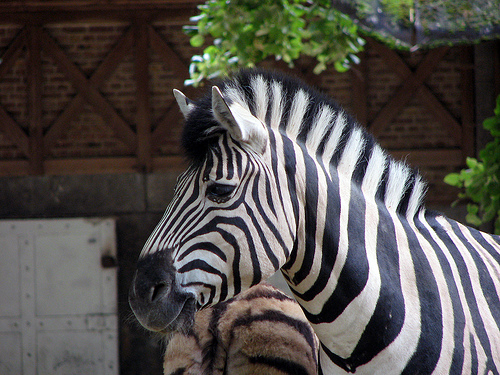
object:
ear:
[172, 87, 206, 132]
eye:
[204, 184, 239, 199]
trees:
[188, 0, 498, 221]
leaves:
[181, 0, 497, 230]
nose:
[122, 248, 175, 318]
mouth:
[137, 301, 194, 338]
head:
[130, 83, 302, 335]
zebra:
[109, 66, 499, 373]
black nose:
[124, 245, 171, 308]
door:
[6, 213, 124, 373]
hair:
[181, 67, 429, 218]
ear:
[212, 72, 265, 144]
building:
[6, 7, 493, 367]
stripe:
[269, 141, 500, 375]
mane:
[172, 74, 434, 221]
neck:
[310, 157, 398, 352]